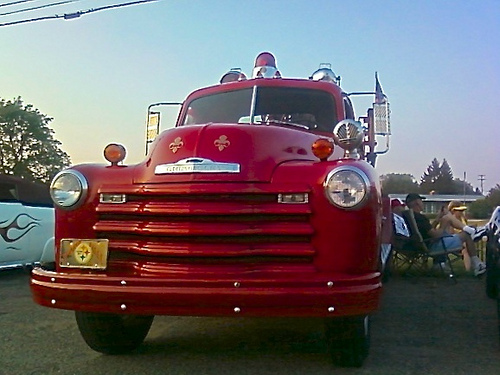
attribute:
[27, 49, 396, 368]
truck — red, parked, a fire truck, antique, large, fire truck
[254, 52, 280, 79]
siren light — a siren, large, red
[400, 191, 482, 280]
man — sitting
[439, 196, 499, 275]
woman — sitting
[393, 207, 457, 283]
chair — plastic, folding chair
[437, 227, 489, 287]
chair — folding chair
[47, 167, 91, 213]
headlight — round, chrome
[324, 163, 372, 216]
headlight — round, chrome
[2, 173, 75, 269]
car — white, older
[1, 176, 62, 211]
top — black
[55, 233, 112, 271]
tag — yellow, gold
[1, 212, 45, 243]
flame design — red, painted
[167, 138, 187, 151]
fleurs-de-lis — gold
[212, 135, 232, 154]
fleurs-de-lis — gold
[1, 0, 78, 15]
line — power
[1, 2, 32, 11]
line — power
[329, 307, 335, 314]
stud — silver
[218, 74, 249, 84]
light — circle, chrome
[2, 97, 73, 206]
tree — tall, green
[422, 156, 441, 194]
tree — tall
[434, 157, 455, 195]
tree — tall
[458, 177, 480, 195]
tree — tall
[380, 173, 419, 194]
tree — tall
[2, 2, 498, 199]
sky — blue, clear, white, bright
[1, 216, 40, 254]
design — flame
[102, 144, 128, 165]
light — orange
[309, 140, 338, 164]
light — orange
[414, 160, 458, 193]
trees — evergreen